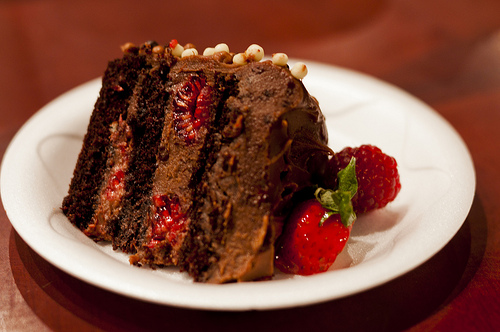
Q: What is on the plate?
A: A slice of chocolate cake.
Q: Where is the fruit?
A: Next to the cake.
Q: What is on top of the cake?
A: Frosting and fruit.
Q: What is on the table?
A: A white plate.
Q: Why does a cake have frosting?
A: For flavor.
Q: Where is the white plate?
A: It is on the brown table.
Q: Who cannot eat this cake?
A: A person who is allergic to chocolate.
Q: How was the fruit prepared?
A: The fruit was sliced.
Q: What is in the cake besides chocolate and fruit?
A: Nuts.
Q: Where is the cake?
A: In a round white bowl.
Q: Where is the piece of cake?
A: On top of a plate.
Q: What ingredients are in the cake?
A: Strawberries and chocolate.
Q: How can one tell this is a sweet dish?
A: The dish has strawberries, chocolate, and frosting.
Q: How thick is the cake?
A: It has three layers.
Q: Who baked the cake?
A: Unable to determine.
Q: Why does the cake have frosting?
A: The frosting sweetens and beautifies the cake.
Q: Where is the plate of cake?
A: It is sitting on a table or counter.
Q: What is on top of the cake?
A: Fruit.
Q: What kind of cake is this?
A: Chocolate with strawberries.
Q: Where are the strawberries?
A: Top of cake.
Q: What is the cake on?
A: Saucer.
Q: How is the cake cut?
A: Sliced.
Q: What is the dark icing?
A: Chocolate.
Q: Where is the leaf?
A: Attached to strawberry.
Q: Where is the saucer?
A: On table.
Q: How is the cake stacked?
A: 3 layers.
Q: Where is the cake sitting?
A: A plate.